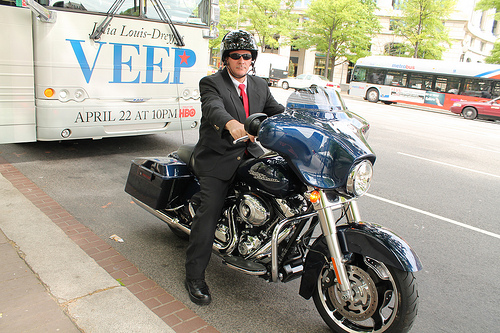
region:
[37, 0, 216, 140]
front of bus on street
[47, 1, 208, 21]
bottom of bus windshield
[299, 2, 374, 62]
green leaves on tree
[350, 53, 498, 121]
side of bus on street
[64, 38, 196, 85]
blue word with red star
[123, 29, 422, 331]
man sitting on motorbike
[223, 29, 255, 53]
reflection on black helmet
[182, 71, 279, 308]
black suit with red tie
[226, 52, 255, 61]
sunglasses on man's face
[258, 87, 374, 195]
blue front of motorbike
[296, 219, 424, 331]
front motorcycle wheel with a shiny blue fender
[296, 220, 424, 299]
shiny blue motorcycle front fender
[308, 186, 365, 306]
shiny metal motorcycle fork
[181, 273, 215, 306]
man's right black dress shoe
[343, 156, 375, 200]
motorcycle front headlight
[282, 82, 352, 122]
small motorcycle front windshield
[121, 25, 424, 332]
man in a suit sitting on a parked motorcycle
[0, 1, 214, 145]
front of a bus advertising the show VEEP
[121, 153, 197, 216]
motorcycle rear storage bin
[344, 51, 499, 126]
mostly white and red city bus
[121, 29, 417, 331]
man on motorcycle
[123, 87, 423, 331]
blue and black motorcycle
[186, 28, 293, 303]
man in suit with helmet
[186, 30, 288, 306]
man in a suit with a helmet and sunglasses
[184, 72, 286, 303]
black suit with white shirt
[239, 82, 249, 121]
red neck tie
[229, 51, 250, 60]
black sunglasses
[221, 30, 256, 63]
shiny black helmet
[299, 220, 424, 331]
motorcycle front wheel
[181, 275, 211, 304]
black shoe on pavement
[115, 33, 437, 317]
man riding a motorcycle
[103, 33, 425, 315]
man in a suit on motorcycle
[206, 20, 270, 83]
man wearing black sun glasses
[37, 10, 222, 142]
advertisement on from of bus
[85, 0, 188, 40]
windshield wipers on front of bus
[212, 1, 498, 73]
tall green trees lining street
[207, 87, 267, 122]
solid red tie around man's neck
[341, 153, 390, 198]
large headlight on fron of motorcycyle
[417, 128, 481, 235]
white lines painted on street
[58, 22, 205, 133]
advertisement for veep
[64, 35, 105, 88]
The letter is blue.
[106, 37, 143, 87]
The letter is blue.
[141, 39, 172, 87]
The letter is blue.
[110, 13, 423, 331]
The man is riding a motorcycle.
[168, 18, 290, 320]
The man is wearing a suit.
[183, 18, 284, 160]
The man is wearing a helmet.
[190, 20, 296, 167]
The man is wearing sunglasses.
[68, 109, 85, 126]
The letter is black.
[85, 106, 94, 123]
The letter is black.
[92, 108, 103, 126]
The letter is black.